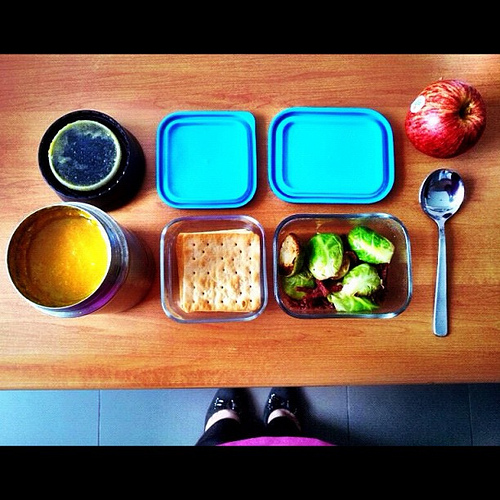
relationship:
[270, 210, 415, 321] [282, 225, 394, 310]
bowl with vegetables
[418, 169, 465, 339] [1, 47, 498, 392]
spoon on table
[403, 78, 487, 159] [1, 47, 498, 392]
apple on table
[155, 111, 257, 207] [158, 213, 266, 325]
lid above bowl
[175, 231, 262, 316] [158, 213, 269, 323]
bread in bowl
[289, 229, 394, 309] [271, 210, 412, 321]
salad in bowl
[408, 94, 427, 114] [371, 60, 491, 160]
sticker on apple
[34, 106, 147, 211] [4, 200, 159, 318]
lid to thermos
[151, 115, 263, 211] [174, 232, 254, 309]
lid that covers crackers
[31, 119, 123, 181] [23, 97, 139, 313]
lid for cup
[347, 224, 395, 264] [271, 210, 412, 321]
lettuce in bowl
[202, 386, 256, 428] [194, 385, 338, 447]
shoe of female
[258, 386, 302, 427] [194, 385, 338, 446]
shoe of female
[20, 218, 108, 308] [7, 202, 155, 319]
soup in cup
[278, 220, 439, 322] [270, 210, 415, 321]
vegetables in bowl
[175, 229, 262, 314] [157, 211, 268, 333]
bread in container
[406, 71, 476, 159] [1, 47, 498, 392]
apple on table